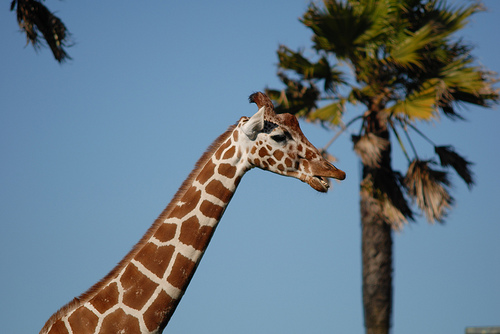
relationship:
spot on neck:
[84, 276, 126, 312] [44, 159, 252, 331]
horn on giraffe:
[244, 88, 269, 118] [37, 90, 349, 333]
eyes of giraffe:
[268, 128, 287, 147] [37, 90, 349, 333]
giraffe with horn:
[37, 90, 349, 333] [246, 90, 276, 113]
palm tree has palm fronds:
[253, 0, 495, 334] [264, 3, 495, 259]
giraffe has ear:
[30, 90, 353, 330] [242, 104, 267, 135]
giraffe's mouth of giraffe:
[310, 168, 350, 195] [30, 90, 353, 330]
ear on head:
[242, 101, 262, 136] [242, 87, 348, 194]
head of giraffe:
[242, 87, 348, 194] [30, 90, 353, 330]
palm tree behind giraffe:
[253, 0, 495, 334] [30, 90, 353, 330]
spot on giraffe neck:
[204, 159, 225, 190] [33, 95, 348, 329]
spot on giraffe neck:
[178, 213, 202, 250] [55, 169, 251, 311]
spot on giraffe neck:
[160, 249, 196, 299] [77, 153, 239, 322]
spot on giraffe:
[178, 213, 202, 250] [37, 90, 349, 333]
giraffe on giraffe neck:
[37, 90, 349, 333] [37, 157, 254, 333]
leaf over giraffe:
[14, 5, 80, 62] [30, 90, 353, 330]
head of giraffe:
[224, 80, 349, 198] [37, 90, 349, 333]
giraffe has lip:
[30, 90, 353, 330] [310, 178, 333, 194]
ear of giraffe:
[242, 104, 267, 135] [86, 87, 363, 318]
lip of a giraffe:
[313, 163, 349, 180] [30, 90, 353, 330]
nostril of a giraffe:
[321, 160, 335, 172] [30, 90, 353, 330]